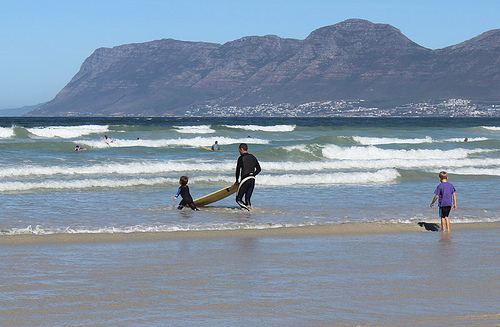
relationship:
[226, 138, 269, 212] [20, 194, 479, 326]
man on beach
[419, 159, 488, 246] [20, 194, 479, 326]
child on beach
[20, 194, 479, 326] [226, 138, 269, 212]
beach has man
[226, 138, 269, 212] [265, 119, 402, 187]
man in water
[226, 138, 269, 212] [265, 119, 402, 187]
man on water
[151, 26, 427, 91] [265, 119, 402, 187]
mountains above water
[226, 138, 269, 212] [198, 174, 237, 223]
man on surfboard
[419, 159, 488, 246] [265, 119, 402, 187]
child near water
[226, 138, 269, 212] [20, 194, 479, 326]
man in beach